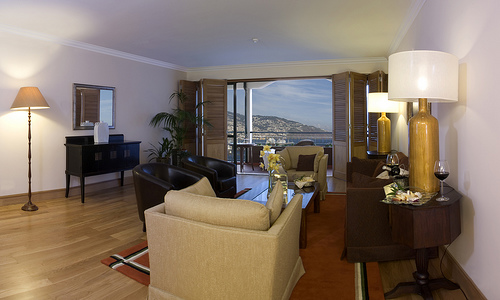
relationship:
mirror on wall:
[71, 80, 117, 130] [0, 30, 192, 202]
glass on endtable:
[431, 159, 451, 205] [384, 186, 459, 299]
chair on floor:
[131, 159, 211, 233] [2, 174, 462, 299]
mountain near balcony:
[225, 112, 325, 138] [231, 157, 337, 175]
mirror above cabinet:
[71, 80, 117, 130] [64, 131, 142, 202]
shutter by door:
[176, 79, 229, 161] [226, 81, 237, 166]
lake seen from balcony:
[237, 137, 332, 147] [231, 157, 337, 175]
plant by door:
[153, 90, 218, 153] [226, 81, 237, 166]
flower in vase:
[260, 142, 280, 167] [264, 168, 284, 201]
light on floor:
[12, 86, 49, 213] [2, 174, 462, 299]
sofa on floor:
[343, 153, 438, 264] [2, 174, 462, 299]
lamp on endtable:
[386, 50, 458, 197] [384, 186, 459, 299]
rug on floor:
[103, 190, 384, 298] [2, 174, 462, 299]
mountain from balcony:
[225, 112, 325, 138] [231, 157, 337, 175]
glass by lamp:
[431, 159, 451, 205] [386, 50, 458, 197]